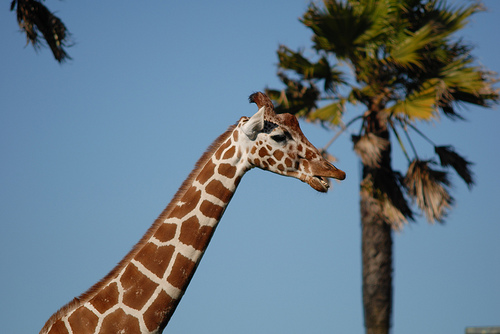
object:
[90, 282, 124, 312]
spot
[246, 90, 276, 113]
horn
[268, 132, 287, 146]
eyes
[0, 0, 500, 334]
sky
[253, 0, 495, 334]
palm tree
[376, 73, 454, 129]
palm fronds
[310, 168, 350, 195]
giraffe's mouth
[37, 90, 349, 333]
giraffe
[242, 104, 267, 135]
ear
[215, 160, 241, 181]
spot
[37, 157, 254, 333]
giraffe neck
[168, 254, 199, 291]
spot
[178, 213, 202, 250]
spot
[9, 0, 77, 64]
leaf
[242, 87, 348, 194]
head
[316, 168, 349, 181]
lip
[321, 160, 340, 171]
nostril